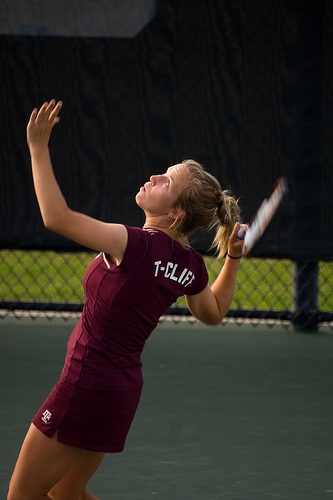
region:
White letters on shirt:
[141, 249, 196, 292]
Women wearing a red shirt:
[60, 151, 226, 410]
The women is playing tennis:
[19, 136, 273, 493]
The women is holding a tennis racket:
[19, 106, 278, 463]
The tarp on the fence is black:
[10, 98, 326, 278]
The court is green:
[26, 303, 314, 483]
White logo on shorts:
[33, 405, 59, 427]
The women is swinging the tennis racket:
[9, 114, 279, 464]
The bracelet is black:
[225, 249, 251, 267]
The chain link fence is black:
[14, 242, 326, 331]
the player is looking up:
[25, 96, 331, 444]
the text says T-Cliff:
[147, 247, 209, 307]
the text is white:
[145, 249, 228, 309]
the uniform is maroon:
[64, 196, 239, 499]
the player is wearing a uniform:
[20, 188, 221, 482]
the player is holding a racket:
[131, 139, 300, 341]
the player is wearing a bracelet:
[220, 243, 251, 272]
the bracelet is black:
[227, 242, 255, 274]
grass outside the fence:
[234, 258, 273, 344]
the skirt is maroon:
[4, 350, 182, 493]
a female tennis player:
[0, 100, 288, 498]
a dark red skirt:
[32, 364, 142, 455]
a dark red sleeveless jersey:
[57, 228, 205, 376]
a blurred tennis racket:
[237, 175, 290, 258]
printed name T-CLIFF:
[148, 253, 197, 292]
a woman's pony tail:
[212, 186, 239, 256]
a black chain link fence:
[0, 61, 330, 330]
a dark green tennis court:
[2, 317, 328, 496]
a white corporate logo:
[40, 407, 51, 423]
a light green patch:
[0, 249, 330, 307]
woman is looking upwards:
[100, 110, 275, 257]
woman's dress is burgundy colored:
[12, 190, 208, 443]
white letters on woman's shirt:
[134, 248, 210, 298]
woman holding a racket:
[233, 173, 295, 248]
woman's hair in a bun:
[184, 164, 269, 242]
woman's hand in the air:
[21, 68, 105, 224]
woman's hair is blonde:
[174, 150, 248, 270]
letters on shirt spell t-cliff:
[144, 245, 204, 294]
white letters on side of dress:
[35, 399, 58, 428]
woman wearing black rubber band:
[214, 243, 256, 266]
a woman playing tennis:
[5, 97, 287, 497]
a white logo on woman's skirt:
[39, 408, 54, 426]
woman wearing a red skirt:
[33, 376, 142, 451]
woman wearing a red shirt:
[62, 214, 209, 380]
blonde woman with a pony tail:
[134, 151, 243, 255]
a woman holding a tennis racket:
[231, 159, 286, 266]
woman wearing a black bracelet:
[225, 250, 244, 263]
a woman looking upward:
[133, 136, 241, 242]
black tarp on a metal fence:
[4, 34, 329, 328]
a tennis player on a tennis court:
[4, 99, 327, 494]